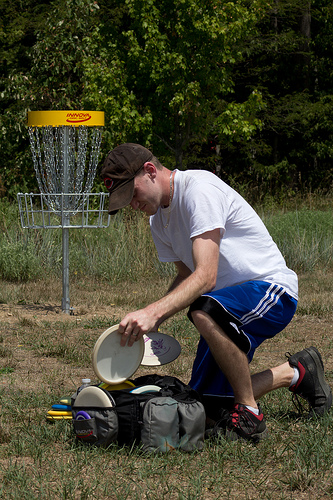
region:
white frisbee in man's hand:
[93, 323, 145, 384]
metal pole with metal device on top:
[13, 108, 109, 317]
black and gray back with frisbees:
[72, 374, 207, 453]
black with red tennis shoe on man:
[285, 346, 331, 417]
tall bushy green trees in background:
[1, 0, 331, 206]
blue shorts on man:
[188, 278, 298, 395]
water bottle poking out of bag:
[78, 378, 90, 391]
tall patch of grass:
[1, 189, 332, 283]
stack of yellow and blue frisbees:
[46, 397, 73, 420]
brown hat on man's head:
[101, 142, 152, 213]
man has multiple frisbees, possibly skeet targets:
[21, 142, 332, 457]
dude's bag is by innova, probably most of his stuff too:
[64, 368, 215, 458]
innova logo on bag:
[71, 426, 95, 441]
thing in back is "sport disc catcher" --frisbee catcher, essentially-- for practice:
[9, 100, 117, 320]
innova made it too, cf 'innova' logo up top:
[57, 109, 90, 121]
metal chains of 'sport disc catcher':
[15, 124, 112, 215]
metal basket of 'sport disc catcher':
[11, 188, 112, 228]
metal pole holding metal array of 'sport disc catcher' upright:
[54, 226, 73, 310]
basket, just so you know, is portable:
[3, 186, 113, 225]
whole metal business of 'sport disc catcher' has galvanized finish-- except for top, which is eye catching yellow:
[9, 108, 114, 312]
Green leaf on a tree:
[214, 82, 247, 121]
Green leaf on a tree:
[259, 165, 291, 195]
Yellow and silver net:
[10, 76, 122, 298]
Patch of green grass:
[6, 456, 27, 493]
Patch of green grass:
[42, 467, 60, 493]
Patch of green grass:
[88, 472, 115, 493]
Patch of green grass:
[128, 460, 151, 492]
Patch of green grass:
[161, 457, 195, 490]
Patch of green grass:
[211, 438, 250, 457]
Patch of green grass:
[280, 450, 307, 498]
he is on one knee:
[102, 165, 252, 436]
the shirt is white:
[200, 190, 246, 238]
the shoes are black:
[281, 343, 331, 419]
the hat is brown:
[105, 153, 134, 172]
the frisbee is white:
[87, 319, 152, 378]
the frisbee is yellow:
[47, 410, 66, 421]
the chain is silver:
[29, 130, 60, 167]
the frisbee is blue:
[51, 402, 71, 412]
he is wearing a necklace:
[163, 165, 175, 226]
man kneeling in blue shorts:
[198, 282, 296, 349]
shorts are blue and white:
[221, 295, 256, 324]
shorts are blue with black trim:
[172, 290, 287, 357]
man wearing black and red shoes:
[212, 416, 242, 434]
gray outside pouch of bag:
[137, 404, 229, 447]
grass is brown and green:
[64, 458, 101, 485]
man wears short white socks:
[279, 357, 290, 392]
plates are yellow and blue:
[43, 394, 71, 421]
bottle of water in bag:
[73, 376, 106, 404]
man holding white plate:
[80, 352, 144, 370]